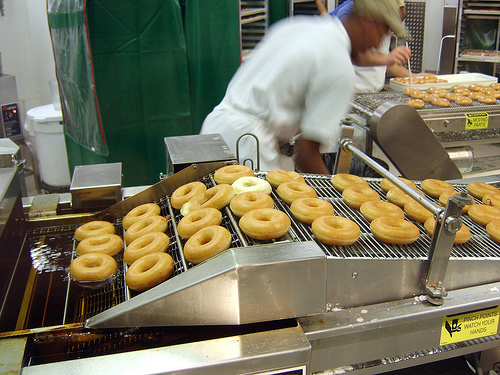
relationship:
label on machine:
[437, 313, 483, 347] [5, 127, 484, 373]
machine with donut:
[5, 127, 484, 373] [215, 159, 254, 186]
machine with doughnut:
[5, 127, 484, 373] [230, 175, 274, 194]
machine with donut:
[5, 127, 484, 373] [223, 186, 281, 219]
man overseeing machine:
[196, 0, 406, 177] [343, 66, 483, 184]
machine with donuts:
[343, 66, 483, 184] [402, 81, 483, 115]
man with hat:
[196, 0, 406, 177] [346, 0, 416, 45]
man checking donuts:
[325, 0, 436, 96] [394, 72, 447, 92]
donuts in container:
[394, 72, 447, 87] [389, 67, 483, 97]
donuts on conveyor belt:
[53, 160, 279, 302] [69, 165, 481, 335]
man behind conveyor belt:
[188, 3, 424, 173] [69, 165, 481, 335]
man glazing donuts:
[325, 0, 436, 96] [389, 69, 447, 86]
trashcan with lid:
[16, 100, 71, 190] [20, 100, 64, 124]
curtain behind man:
[41, 1, 243, 191] [188, 3, 424, 173]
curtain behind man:
[41, 1, 243, 191] [318, 2, 413, 173]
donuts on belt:
[57, 199, 170, 294] [0, 160, 499, 338]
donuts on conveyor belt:
[141, 185, 401, 251] [62, 163, 470, 321]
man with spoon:
[322, 0, 409, 98] [380, 38, 423, 96]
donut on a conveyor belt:
[294, 196, 331, 226] [72, 160, 497, 318]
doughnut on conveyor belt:
[70, 253, 114, 280] [3, 164, 498, 335]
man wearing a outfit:
[196, 0, 406, 177] [202, 15, 346, 174]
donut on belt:
[236, 207, 290, 240] [12, 165, 496, 317]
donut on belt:
[369, 214, 423, 246] [4, 160, 498, 294]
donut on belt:
[217, 164, 256, 181] [12, 165, 496, 317]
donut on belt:
[349, 183, 379, 205] [12, 165, 496, 317]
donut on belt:
[238, 209, 290, 236] [7, 179, 498, 303]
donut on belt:
[78, 230, 123, 255] [7, 179, 498, 303]